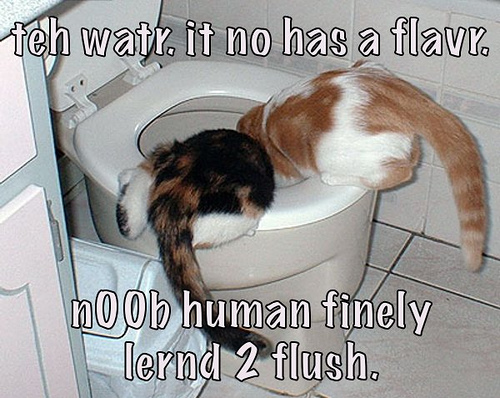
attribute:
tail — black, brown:
[149, 223, 235, 325]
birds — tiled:
[403, 11, 488, 71]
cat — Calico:
[101, 107, 301, 367]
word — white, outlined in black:
[176, 16, 216, 67]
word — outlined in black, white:
[223, 17, 274, 64]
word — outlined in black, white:
[352, 24, 386, 65]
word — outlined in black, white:
[270, 337, 368, 382]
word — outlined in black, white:
[179, 286, 313, 332]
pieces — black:
[67, 73, 86, 95]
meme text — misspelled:
[12, 15, 498, 70]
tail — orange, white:
[426, 91, 491, 278]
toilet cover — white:
[74, 41, 389, 244]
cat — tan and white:
[82, 100, 302, 366]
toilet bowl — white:
[74, 56, 395, 392]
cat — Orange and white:
[249, 56, 486, 273]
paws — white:
[316, 163, 415, 190]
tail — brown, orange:
[421, 107, 487, 268]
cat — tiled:
[247, 61, 499, 267]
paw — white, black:
[115, 157, 150, 242]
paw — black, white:
[201, 208, 266, 246]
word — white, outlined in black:
[224, 23, 274, 59]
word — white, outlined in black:
[272, 342, 364, 383]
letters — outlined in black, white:
[7, 10, 495, 70]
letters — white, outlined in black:
[66, 280, 436, 385]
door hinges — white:
[48, 217, 65, 262]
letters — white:
[390, 14, 407, 54]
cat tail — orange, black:
[154, 178, 279, 361]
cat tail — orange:
[371, 67, 490, 278]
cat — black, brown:
[106, 65, 453, 374]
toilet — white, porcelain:
[113, 117, 407, 394]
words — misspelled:
[7, 10, 496, 65]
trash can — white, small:
[66, 229, 211, 396]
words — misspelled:
[69, 287, 433, 382]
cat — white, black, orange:
[114, 129, 276, 358]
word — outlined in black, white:
[320, 287, 431, 335]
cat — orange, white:
[232, 51, 499, 276]